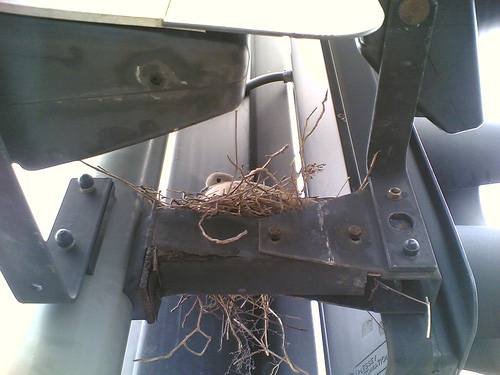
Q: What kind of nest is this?
A: Bird's nest.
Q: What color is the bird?
A: White.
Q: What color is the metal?
A: Black.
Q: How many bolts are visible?
A: Six.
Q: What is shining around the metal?
A: Sunlight.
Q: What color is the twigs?
A: Brown.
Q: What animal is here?
A: Bird.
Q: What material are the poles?
A: Metal.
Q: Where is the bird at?
A: Nest.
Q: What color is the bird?
A: White.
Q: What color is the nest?
A: Brown.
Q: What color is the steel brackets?
A: Black.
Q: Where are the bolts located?
A: In the brackets.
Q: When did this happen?
A: During the day time.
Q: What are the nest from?
A: Twigs.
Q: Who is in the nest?
A: A dove.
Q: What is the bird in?
A: A nest.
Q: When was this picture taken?
A: Daytime.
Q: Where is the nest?
A: On a metal beam.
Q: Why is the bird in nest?
A: To protect eggs.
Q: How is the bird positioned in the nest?
A: Laying.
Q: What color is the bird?
A: White.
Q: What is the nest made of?
A: Twigs.